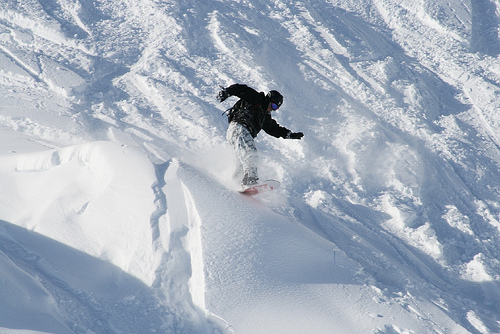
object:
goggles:
[272, 99, 283, 105]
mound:
[10, 164, 213, 317]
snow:
[1, 1, 30, 36]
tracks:
[36, 77, 72, 96]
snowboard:
[237, 177, 279, 201]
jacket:
[222, 83, 292, 139]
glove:
[289, 131, 304, 140]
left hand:
[289, 131, 307, 140]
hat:
[267, 89, 284, 111]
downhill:
[367, 216, 500, 334]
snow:
[394, 66, 445, 98]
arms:
[226, 83, 257, 98]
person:
[212, 81, 305, 197]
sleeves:
[224, 83, 261, 96]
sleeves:
[261, 117, 290, 139]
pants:
[225, 126, 260, 186]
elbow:
[233, 82, 243, 88]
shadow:
[2, 269, 93, 332]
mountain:
[1, 2, 500, 332]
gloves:
[216, 89, 230, 102]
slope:
[231, 196, 319, 322]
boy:
[211, 83, 305, 188]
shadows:
[279, 243, 337, 280]